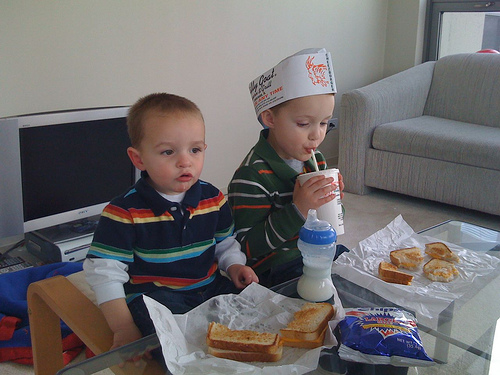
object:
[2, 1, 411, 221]
part of wall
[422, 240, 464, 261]
edge of bread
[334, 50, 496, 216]
edge of chair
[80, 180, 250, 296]
part of shirt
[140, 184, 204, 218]
part of collar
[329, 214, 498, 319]
wrapper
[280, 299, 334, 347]
part of food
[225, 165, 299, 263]
edge of sleeve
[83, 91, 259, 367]
child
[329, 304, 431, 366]
bag of potato chips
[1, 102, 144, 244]
television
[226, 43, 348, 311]
child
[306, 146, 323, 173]
straw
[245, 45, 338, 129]
paper hat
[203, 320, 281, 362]
sandwich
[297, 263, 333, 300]
milk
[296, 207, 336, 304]
sippy cup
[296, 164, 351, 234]
cup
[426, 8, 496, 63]
window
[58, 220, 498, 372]
coffee table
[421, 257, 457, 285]
lunch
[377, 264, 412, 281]
cheese